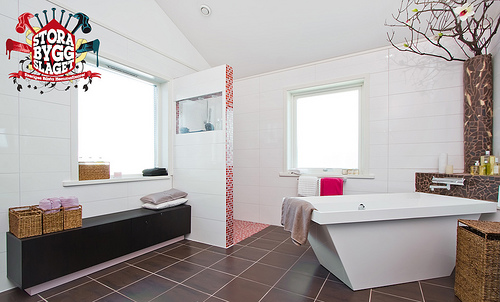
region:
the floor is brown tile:
[150, 249, 308, 300]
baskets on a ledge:
[10, 198, 100, 263]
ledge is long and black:
[17, 192, 197, 279]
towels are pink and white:
[288, 171, 351, 196]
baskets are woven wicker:
[6, 202, 83, 232]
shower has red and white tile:
[224, 65, 262, 245]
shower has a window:
[174, 93, 226, 148]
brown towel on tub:
[277, 189, 324, 251]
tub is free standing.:
[281, 182, 478, 288]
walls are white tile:
[368, 65, 461, 168]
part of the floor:
[236, 240, 278, 286]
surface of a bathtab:
[352, 230, 398, 262]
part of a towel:
[277, 220, 307, 242]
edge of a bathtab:
[371, 206, 415, 219]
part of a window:
[314, 111, 344, 147]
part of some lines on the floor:
[241, 255, 297, 285]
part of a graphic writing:
[30, 19, 64, 91]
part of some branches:
[413, 4, 460, 68]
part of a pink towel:
[318, 178, 333, 196]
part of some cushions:
[149, 188, 183, 203]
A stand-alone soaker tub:
[291, 195, 491, 289]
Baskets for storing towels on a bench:
[12, 191, 90, 248]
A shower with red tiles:
[166, 52, 266, 259]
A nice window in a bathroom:
[286, 76, 376, 192]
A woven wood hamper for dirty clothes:
[457, 213, 498, 300]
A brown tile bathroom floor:
[165, 247, 282, 300]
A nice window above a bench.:
[77, 57, 173, 189]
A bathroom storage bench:
[11, 187, 195, 288]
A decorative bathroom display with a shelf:
[399, 46, 499, 192]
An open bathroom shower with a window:
[164, 57, 274, 266]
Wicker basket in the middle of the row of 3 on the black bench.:
[38, 202, 62, 229]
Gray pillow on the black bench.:
[141, 192, 188, 201]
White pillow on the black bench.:
[148, 200, 190, 207]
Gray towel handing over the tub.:
[273, 196, 313, 244]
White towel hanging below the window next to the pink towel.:
[298, 173, 317, 195]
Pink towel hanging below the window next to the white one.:
[319, 174, 344, 193]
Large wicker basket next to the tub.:
[456, 213, 498, 300]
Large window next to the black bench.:
[76, 73, 168, 177]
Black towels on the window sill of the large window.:
[144, 166, 168, 176]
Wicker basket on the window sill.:
[78, 156, 110, 181]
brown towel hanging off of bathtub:
[267, 187, 317, 242]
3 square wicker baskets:
[13, 180, 102, 243]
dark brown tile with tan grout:
[111, 260, 238, 296]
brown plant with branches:
[355, 4, 498, 136]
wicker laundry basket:
[431, 200, 499, 278]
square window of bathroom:
[270, 60, 398, 209]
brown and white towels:
[132, 182, 202, 226]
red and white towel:
[300, 174, 360, 196]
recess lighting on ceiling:
[186, 4, 224, 36]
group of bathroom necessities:
[464, 151, 499, 179]